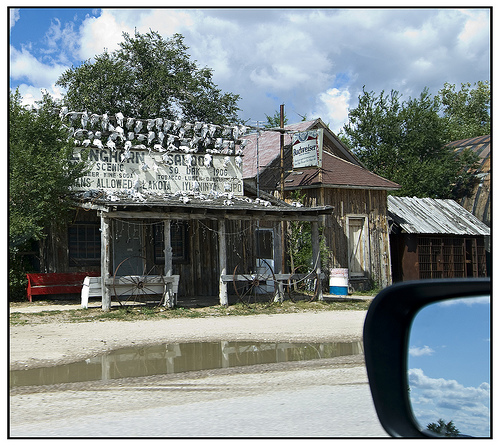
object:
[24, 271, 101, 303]
bench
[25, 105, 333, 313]
store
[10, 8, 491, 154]
blue sky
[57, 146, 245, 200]
sign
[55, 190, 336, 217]
roof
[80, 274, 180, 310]
bench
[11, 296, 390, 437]
road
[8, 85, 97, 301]
tree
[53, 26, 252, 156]
tree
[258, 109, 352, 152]
tree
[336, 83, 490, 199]
tree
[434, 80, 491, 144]
tree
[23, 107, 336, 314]
building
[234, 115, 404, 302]
building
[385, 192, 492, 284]
building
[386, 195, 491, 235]
roof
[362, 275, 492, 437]
mirror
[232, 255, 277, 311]
wheel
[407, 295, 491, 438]
sky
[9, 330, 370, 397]
puddle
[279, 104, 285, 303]
wooden post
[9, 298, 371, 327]
grass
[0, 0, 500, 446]
photo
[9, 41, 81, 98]
clouds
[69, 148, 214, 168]
longhorn saloon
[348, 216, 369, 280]
doorway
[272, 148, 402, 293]
shack